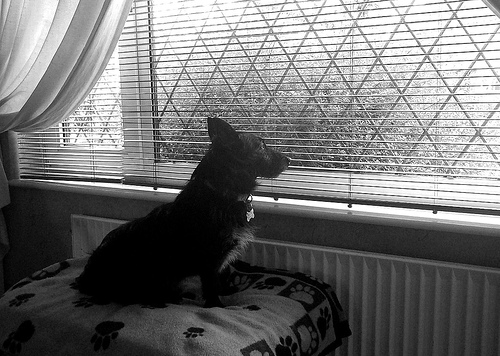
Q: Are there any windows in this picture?
A: Yes, there is a window.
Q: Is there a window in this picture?
A: Yes, there is a window.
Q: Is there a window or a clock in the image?
A: Yes, there is a window.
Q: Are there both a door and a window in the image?
A: No, there is a window but no doors.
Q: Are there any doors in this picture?
A: No, there are no doors.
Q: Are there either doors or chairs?
A: No, there are no doors or chairs.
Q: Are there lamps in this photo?
A: No, there are no lamps.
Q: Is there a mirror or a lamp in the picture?
A: No, there are no lamps or mirrors.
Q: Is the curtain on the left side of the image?
A: Yes, the curtain is on the left of the image.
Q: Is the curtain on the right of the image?
A: No, the curtain is on the left of the image.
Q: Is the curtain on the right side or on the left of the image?
A: The curtain is on the left of the image.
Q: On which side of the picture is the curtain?
A: The curtain is on the left of the image.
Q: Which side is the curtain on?
A: The curtain is on the left of the image.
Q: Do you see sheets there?
A: No, there are no sheets.